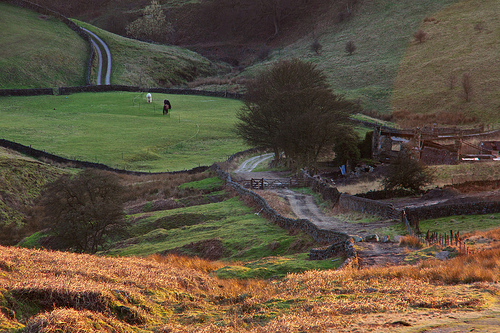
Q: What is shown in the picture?
A: A farm.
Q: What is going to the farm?
A: A dirt road.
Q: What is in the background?
A: A valley.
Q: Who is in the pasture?
A: Three cows.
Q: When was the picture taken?
A: In the day.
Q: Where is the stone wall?
A: Along the road.